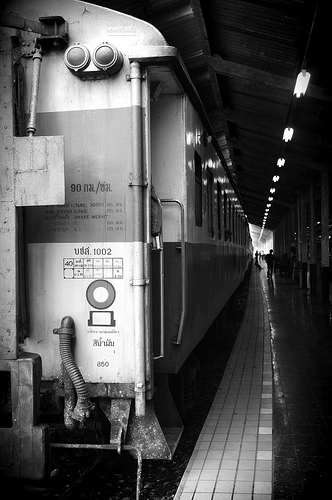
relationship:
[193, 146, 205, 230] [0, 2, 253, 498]
window on train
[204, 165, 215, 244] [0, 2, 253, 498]
window on train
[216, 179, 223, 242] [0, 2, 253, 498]
window on train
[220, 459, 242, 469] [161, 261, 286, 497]
tile on floor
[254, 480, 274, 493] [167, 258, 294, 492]
tile in floor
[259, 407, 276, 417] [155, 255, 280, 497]
tile inside floor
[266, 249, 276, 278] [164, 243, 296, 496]
person on platform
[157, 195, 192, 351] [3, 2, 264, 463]
bar inside train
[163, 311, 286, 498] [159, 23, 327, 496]
tiles on platform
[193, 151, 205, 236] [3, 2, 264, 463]
window on train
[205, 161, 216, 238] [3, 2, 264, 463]
window on train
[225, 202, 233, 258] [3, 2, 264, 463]
window on train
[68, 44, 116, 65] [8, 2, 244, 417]
light on train